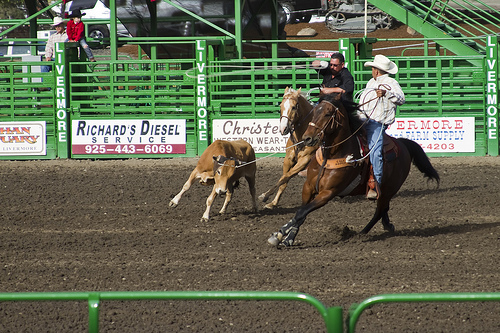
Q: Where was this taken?
A: Rodeo.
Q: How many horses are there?
A: 2.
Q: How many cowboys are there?
A: 4.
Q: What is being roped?
A: Calf.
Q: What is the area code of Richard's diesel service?
A: 925.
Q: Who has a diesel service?
A: Richard.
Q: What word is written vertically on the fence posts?
A: Livermore.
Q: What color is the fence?
A: Green.